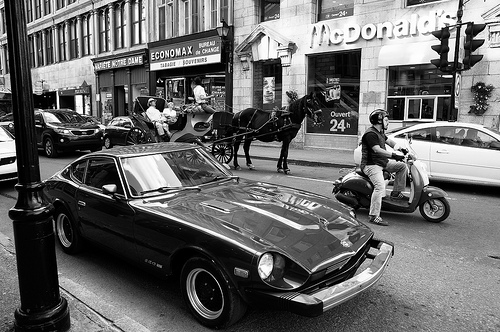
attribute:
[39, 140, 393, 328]
car — vintage, parked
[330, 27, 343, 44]
letter — white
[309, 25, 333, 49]
letter — white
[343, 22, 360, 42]
letter — white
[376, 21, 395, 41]
letter — white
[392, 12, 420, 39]
letter — white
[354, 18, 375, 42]
letter — white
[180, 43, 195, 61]
letter — white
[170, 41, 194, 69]
letter — white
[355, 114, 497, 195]
car — white, small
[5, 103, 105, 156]
truck — black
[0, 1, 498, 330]
picture — black, white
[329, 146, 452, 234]
scooter — small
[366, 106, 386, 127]
helmet — black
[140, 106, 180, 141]
shirt — white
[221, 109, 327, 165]
horse — black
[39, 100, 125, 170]
suv — black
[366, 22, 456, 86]
sign — white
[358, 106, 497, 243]
car — white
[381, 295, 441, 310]
stains — dark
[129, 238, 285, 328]
rims — silver, black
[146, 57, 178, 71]
letter — white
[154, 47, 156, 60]
letter — white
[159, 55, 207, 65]
letter — white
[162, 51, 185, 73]
letter — white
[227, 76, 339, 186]
horse — black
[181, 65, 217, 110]
person — highest, looking back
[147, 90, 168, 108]
hat — light colored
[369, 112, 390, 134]
helmet — black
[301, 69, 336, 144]
head — black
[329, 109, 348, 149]
number — 24, large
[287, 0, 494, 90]
lettering — McDonalds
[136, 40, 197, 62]
word — ECONOMAX 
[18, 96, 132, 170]
suv — black